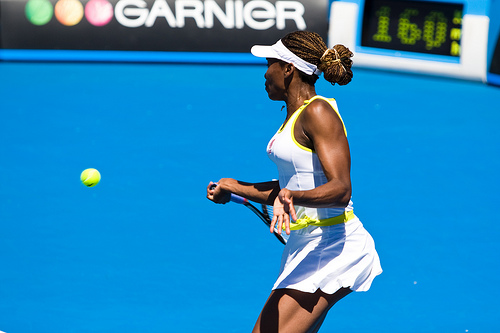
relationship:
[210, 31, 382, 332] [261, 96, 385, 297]
woman wearing dress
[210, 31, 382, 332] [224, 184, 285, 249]
woman holding tennis racket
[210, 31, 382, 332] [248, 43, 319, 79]
woman wearing hat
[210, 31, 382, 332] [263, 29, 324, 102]
woman has head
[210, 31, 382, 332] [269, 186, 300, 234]
woman has hand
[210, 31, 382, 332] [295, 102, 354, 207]
woman has arm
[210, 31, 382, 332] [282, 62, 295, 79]
woman has ear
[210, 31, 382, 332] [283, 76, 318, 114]
woman has neck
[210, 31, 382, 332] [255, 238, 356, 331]
woman has leg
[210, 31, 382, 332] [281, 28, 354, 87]
woman has hair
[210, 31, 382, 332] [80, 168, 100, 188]
woman ready to hit ball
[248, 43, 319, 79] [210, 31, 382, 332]
hat worn by woman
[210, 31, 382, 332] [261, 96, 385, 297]
woman wears dress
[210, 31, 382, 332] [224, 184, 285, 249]
woman holds tennis racket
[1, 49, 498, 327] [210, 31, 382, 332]
wall on side of woman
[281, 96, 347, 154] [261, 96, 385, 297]
trim on top of dress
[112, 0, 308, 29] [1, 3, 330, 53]
print written on background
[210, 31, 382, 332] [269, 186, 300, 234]
woman has left hand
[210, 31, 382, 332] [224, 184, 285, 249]
woman swinging tennis racket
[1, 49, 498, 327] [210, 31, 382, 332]
wall behind woman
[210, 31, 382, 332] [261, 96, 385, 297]
woman has dress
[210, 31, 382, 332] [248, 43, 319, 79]
woman has hat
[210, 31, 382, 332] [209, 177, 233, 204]
woman has right hand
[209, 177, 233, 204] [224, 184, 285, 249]
right hand holding tennis racket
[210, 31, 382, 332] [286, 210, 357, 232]
woman has belt